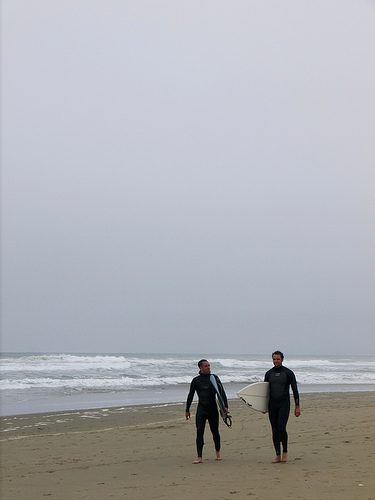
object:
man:
[266, 351, 301, 463]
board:
[234, 379, 272, 413]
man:
[184, 356, 231, 465]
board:
[214, 396, 233, 427]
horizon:
[2, 341, 373, 361]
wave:
[6, 355, 128, 367]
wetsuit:
[262, 366, 297, 457]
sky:
[0, 3, 375, 361]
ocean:
[4, 351, 374, 414]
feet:
[275, 451, 280, 461]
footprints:
[226, 488, 238, 494]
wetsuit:
[185, 372, 226, 459]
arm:
[264, 369, 268, 378]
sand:
[4, 393, 372, 496]